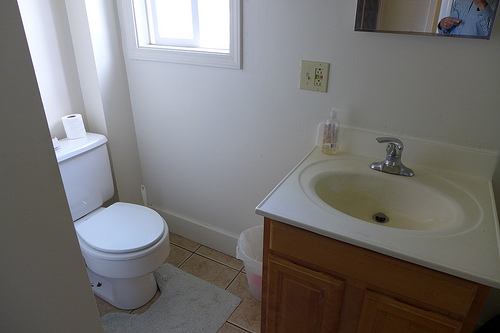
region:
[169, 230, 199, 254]
beige tile on floor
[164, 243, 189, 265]
beige tile on floor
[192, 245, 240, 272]
beige tile on floor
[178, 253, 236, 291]
beige tile on floor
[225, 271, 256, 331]
beige tile on floor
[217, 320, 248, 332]
beige tile on floor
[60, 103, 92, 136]
The roll of toilet paper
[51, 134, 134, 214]
The tank for the toilet.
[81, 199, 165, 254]
The lid for the toilet.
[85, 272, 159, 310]
The base of the toilet.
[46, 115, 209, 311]
The toilet is white.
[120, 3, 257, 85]
The window next to the toilet.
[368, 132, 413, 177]
The sink faucet is chrome.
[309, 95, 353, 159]
The bottle of soap on the sink.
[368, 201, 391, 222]
The stopper in the sink is chrome.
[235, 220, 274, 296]
There is a trashcan near the sink.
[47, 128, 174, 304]
white toilet in the bathroom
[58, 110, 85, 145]
white paper in the bathroom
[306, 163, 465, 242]
white sink in the bathroom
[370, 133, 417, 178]
silver faucet in the bathroom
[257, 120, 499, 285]
white counter in the bathroom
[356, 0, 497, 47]
silver mirror in the bathroom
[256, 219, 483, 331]
brown cabinet in the bathroom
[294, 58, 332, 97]
white switch in the bathroom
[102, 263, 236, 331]
white rug in the bathroom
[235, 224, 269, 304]
white basket in the bathroom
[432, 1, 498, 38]
person in blue shirt reflected in bathroom mirror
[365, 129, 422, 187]
silver sink faucet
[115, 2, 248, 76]
window in bathroom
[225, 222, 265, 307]
trashcan with white liner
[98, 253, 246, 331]
small mat in front of toilet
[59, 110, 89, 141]
roll of toilet tissue on top of toilet tank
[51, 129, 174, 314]
white toilet in corner of bathroom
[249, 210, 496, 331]
wooden cabinets underneath sink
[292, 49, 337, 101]
tan wall outlet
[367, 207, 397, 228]
circular drain in bathroom sink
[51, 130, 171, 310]
a clean white toilet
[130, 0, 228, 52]
an open window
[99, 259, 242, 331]
a gray floor mat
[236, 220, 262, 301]
a trashcan with a trash bag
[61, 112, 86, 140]
a roll of toilet paper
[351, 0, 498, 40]
a mirror on the wall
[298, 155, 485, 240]
a clean bathroom sink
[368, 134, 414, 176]
a metal faucet above the sink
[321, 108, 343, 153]
a bottle of hand soap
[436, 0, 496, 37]
reflection of a person in the mirror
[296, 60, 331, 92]
Outlet plate on a wall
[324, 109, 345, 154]
Liquid hand soap on sink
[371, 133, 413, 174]
Silver faucett of sink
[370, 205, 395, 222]
Drain in bowl of sink